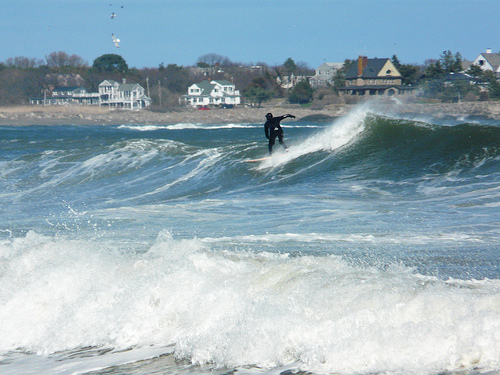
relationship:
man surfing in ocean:
[262, 112, 298, 158] [2, 114, 498, 375]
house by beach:
[177, 72, 244, 109] [3, 99, 498, 128]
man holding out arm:
[262, 112, 298, 158] [277, 113, 299, 123]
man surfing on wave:
[262, 112, 298, 158] [20, 99, 500, 204]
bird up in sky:
[108, 34, 128, 51] [2, 2, 500, 67]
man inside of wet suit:
[262, 112, 298, 158] [263, 117, 287, 153]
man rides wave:
[262, 112, 298, 158] [20, 99, 500, 204]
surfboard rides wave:
[242, 153, 279, 165] [20, 99, 500, 204]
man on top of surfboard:
[262, 112, 298, 158] [242, 153, 279, 165]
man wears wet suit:
[262, 112, 298, 158] [263, 117, 287, 153]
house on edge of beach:
[177, 72, 244, 109] [3, 99, 498, 128]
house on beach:
[177, 72, 244, 109] [3, 99, 498, 128]